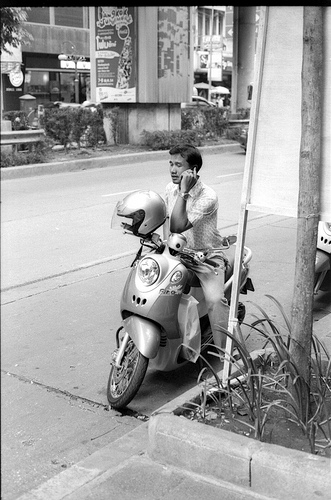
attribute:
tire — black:
[108, 340, 146, 412]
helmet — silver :
[116, 191, 168, 233]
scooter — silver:
[97, 217, 261, 405]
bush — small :
[41, 101, 106, 149]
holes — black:
[115, 285, 154, 314]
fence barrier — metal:
[0, 128, 55, 160]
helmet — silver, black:
[100, 181, 172, 241]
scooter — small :
[108, 214, 258, 404]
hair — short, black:
[168, 142, 203, 170]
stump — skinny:
[293, 127, 329, 225]